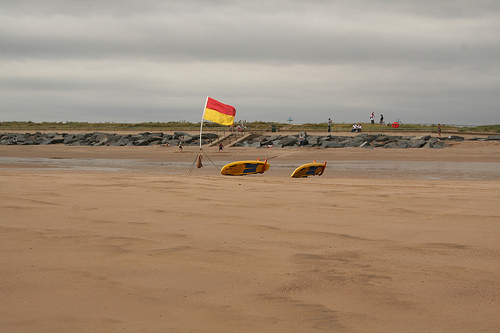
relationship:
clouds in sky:
[0, 0, 499, 126] [384, 14, 498, 98]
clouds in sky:
[0, 0, 499, 126] [11, 7, 296, 120]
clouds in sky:
[0, 0, 499, 126] [1, 3, 498, 122]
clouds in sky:
[0, 0, 499, 126] [13, 18, 251, 74]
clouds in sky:
[47, 7, 420, 94] [3, 3, 496, 139]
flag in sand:
[194, 93, 241, 153] [2, 124, 498, 330]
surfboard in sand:
[219, 158, 271, 173] [0, 170, 497, 329]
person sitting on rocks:
[378, 109, 386, 125] [0, 130, 447, 148]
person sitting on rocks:
[368, 109, 375, 125] [0, 130, 447, 148]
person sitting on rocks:
[323, 116, 335, 133] [0, 130, 447, 148]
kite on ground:
[389, 121, 401, 131] [5, 117, 497, 134]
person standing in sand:
[173, 137, 185, 153] [6, 146, 496, 161]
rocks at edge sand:
[0, 129, 481, 156] [0, 145, 495, 331]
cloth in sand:
[390, 120, 402, 131] [5, 125, 494, 136]